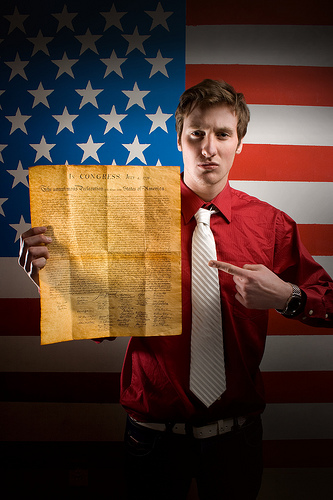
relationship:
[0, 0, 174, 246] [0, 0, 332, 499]
stars on stripes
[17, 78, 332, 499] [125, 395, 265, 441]
man wearing belt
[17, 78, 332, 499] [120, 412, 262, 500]
man wearing jeans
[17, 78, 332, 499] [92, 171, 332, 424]
man wearing shirt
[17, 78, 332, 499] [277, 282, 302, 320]
man has watch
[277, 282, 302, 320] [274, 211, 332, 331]
watch on arm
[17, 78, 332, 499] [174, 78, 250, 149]
man has hair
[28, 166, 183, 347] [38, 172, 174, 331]
paper has writing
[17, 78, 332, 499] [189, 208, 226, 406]
man wearing tie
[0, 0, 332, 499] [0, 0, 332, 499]
stripes has stripes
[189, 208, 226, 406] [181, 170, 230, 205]
tie around neck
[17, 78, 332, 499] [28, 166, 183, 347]
man holding paper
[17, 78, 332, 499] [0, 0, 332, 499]
man in front of stripes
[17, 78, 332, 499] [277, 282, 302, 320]
man wearing watch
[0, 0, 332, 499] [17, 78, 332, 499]
stripes behind man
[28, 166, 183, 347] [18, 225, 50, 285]
paper in right hand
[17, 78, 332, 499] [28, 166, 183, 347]
man pointing at paper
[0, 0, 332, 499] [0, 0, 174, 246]
stripes has stars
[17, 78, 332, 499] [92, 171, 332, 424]
man in shirt